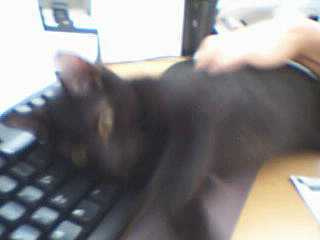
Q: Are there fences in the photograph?
A: No, there are no fences.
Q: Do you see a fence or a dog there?
A: No, there are no fences or dogs.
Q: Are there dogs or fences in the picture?
A: No, there are no fences or dogs.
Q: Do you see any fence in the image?
A: No, there are no fences.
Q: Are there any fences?
A: No, there are no fences.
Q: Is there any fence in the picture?
A: No, there are no fences.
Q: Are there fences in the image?
A: No, there are no fences.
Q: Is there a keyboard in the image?
A: Yes, there is a keyboard.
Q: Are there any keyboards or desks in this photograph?
A: Yes, there is a keyboard.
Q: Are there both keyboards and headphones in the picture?
A: No, there is a keyboard but no headphones.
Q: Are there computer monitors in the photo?
A: No, there are no computer monitors.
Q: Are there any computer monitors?
A: No, there are no computer monitors.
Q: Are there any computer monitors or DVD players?
A: No, there are no computer monitors or DVD players.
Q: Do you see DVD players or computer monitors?
A: No, there are no computer monitors or DVD players.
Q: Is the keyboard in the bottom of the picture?
A: Yes, the keyboard is in the bottom of the image.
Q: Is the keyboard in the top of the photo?
A: No, the keyboard is in the bottom of the image.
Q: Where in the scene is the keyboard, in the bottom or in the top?
A: The keyboard is in the bottom of the image.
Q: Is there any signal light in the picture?
A: No, there are no traffic lights.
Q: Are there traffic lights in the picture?
A: No, there are no traffic lights.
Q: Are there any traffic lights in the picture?
A: No, there are no traffic lights.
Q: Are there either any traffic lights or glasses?
A: No, there are no traffic lights or glasses.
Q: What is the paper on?
A: The paper is on the desk.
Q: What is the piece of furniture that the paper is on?
A: The piece of furniture is a desk.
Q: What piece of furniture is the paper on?
A: The paper is on the desk.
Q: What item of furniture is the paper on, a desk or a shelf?
A: The paper is on a desk.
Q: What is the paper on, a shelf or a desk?
A: The paper is on a desk.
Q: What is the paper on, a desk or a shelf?
A: The paper is on a desk.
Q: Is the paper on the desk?
A: Yes, the paper is on the desk.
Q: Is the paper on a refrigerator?
A: No, the paper is on the desk.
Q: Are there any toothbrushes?
A: No, there are no toothbrushes.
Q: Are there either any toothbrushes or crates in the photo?
A: No, there are no toothbrushes or crates.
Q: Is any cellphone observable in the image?
A: No, there are no cell phones.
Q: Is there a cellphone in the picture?
A: No, there are no cell phones.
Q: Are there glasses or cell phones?
A: No, there are no cell phones or glasses.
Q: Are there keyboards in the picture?
A: Yes, there is a keyboard.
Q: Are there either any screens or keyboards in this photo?
A: Yes, there is a keyboard.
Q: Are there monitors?
A: No, there are no monitors.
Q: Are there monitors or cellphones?
A: No, there are no monitors or cellphones.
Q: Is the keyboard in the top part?
A: No, the keyboard is in the bottom of the image.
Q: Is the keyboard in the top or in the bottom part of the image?
A: The keyboard is in the bottom of the image.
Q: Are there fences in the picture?
A: No, there are no fences.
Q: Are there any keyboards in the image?
A: Yes, there is a keyboard.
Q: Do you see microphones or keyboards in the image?
A: Yes, there is a keyboard.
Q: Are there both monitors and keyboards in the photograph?
A: No, there is a keyboard but no monitors.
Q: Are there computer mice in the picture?
A: No, there are no computer mice.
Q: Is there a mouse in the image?
A: No, there are no computer mice.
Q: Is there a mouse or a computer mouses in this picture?
A: No, there are no computer mice or computer mousess.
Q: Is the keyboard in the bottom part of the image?
A: Yes, the keyboard is in the bottom of the image.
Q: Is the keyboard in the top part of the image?
A: No, the keyboard is in the bottom of the image.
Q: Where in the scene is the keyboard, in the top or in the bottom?
A: The keyboard is in the bottom of the image.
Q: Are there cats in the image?
A: Yes, there is a cat.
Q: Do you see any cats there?
A: Yes, there is a cat.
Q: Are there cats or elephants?
A: Yes, there is a cat.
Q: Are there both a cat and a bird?
A: No, there is a cat but no birds.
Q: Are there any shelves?
A: No, there are no shelves.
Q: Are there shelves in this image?
A: No, there are no shelves.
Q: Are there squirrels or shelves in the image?
A: No, there are no shelves or squirrels.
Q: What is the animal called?
A: The animal is a cat.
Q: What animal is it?
A: The animal is a cat.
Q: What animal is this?
A: This is a cat.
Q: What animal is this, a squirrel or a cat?
A: This is a cat.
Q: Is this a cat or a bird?
A: This is a cat.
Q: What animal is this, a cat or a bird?
A: This is a cat.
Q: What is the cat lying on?
A: The cat is lying on the keyboard.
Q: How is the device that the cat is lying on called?
A: The device is a keyboard.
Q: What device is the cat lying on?
A: The cat is lying on the keyboard.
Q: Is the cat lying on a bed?
A: No, the cat is lying on a keyboard.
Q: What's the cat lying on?
A: The cat is lying on the keyboard.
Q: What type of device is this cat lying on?
A: The cat is lying on the keyboard.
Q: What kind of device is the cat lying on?
A: The cat is lying on the keyboard.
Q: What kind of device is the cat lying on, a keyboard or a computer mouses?
A: The cat is lying on a keyboard.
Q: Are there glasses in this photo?
A: No, there are no glasses.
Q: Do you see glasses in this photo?
A: No, there are no glasses.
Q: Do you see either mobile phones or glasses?
A: No, there are no glasses or mobile phones.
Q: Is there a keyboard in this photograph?
A: Yes, there is a keyboard.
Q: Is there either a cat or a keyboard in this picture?
A: Yes, there is a keyboard.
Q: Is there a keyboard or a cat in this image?
A: Yes, there is a keyboard.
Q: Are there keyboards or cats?
A: Yes, there is a keyboard.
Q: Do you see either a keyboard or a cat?
A: Yes, there is a keyboard.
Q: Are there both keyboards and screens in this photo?
A: No, there is a keyboard but no screens.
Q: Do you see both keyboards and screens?
A: No, there is a keyboard but no screens.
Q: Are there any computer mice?
A: No, there are no computer mice.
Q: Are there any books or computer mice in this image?
A: No, there are no computer mice or books.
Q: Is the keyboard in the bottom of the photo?
A: Yes, the keyboard is in the bottom of the image.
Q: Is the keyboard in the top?
A: No, the keyboard is in the bottom of the image.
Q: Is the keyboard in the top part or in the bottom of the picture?
A: The keyboard is in the bottom of the image.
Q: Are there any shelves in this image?
A: No, there are no shelves.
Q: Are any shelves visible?
A: No, there are no shelves.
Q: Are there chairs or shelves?
A: No, there are no shelves or chairs.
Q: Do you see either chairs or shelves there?
A: No, there are no shelves or chairs.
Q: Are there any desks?
A: Yes, there is a desk.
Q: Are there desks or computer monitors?
A: Yes, there is a desk.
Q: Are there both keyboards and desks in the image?
A: Yes, there are both a desk and a keyboard.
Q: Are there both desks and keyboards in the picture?
A: Yes, there are both a desk and a keyboard.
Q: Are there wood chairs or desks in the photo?
A: Yes, there is a wood desk.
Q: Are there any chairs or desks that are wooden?
A: Yes, the desk is wooden.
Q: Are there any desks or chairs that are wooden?
A: Yes, the desk is wooden.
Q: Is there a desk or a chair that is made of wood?
A: Yes, the desk is made of wood.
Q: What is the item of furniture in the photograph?
A: The piece of furniture is a desk.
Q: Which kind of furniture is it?
A: The piece of furniture is a desk.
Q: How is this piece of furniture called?
A: This is a desk.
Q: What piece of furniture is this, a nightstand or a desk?
A: This is a desk.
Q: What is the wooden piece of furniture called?
A: The piece of furniture is a desk.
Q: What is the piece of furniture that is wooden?
A: The piece of furniture is a desk.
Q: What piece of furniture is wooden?
A: The piece of furniture is a desk.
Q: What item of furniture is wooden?
A: The piece of furniture is a desk.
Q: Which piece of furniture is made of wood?
A: The piece of furniture is a desk.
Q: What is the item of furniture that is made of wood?
A: The piece of furniture is a desk.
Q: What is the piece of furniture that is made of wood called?
A: The piece of furniture is a desk.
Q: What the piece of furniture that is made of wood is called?
A: The piece of furniture is a desk.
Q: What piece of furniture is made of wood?
A: The piece of furniture is a desk.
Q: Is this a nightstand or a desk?
A: This is a desk.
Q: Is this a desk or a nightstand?
A: This is a desk.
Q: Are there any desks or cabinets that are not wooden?
A: No, there is a desk but it is wooden.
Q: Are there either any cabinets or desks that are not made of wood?
A: No, there is a desk but it is made of wood.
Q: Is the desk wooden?
A: Yes, the desk is wooden.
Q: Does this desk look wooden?
A: Yes, the desk is wooden.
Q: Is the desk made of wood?
A: Yes, the desk is made of wood.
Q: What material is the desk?
A: The desk is made of wood.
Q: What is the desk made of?
A: The desk is made of wood.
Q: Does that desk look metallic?
A: No, the desk is wooden.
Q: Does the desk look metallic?
A: No, the desk is wooden.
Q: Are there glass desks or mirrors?
A: No, there is a desk but it is wooden.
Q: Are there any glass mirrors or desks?
A: No, there is a desk but it is wooden.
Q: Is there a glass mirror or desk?
A: No, there is a desk but it is wooden.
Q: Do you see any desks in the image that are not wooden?
A: No, there is a desk but it is wooden.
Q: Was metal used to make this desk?
A: No, the desk is made of wood.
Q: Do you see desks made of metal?
A: No, there is a desk but it is made of wood.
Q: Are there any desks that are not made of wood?
A: No, there is a desk but it is made of wood.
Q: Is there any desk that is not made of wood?
A: No, there is a desk but it is made of wood.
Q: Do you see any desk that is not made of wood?
A: No, there is a desk but it is made of wood.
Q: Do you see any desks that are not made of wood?
A: No, there is a desk but it is made of wood.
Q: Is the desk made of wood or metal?
A: The desk is made of wood.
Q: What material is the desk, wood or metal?
A: The desk is made of wood.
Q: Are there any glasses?
A: No, there are no glasses.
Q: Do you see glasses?
A: No, there are no glasses.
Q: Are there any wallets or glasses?
A: No, there are no glasses or wallets.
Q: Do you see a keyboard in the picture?
A: Yes, there is a keyboard.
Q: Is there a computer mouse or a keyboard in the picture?
A: Yes, there is a keyboard.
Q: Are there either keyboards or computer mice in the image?
A: Yes, there is a keyboard.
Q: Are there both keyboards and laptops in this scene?
A: No, there is a keyboard but no laptops.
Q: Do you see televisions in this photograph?
A: No, there are no televisions.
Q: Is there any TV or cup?
A: No, there are no televisions or cups.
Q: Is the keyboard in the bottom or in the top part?
A: The keyboard is in the bottom of the image.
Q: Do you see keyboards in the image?
A: Yes, there is a keyboard.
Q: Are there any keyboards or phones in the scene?
A: Yes, there is a keyboard.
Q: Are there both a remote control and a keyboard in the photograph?
A: No, there is a keyboard but no remote controls.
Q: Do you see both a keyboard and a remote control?
A: No, there is a keyboard but no remote controls.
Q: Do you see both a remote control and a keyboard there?
A: No, there is a keyboard but no remote controls.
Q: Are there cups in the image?
A: No, there are no cups.